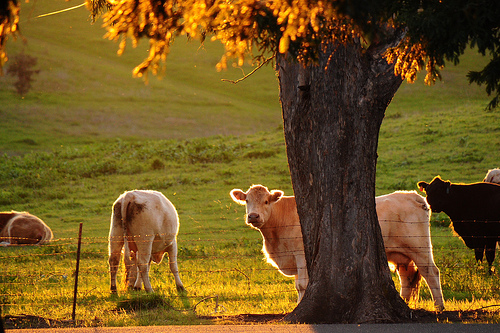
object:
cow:
[417, 174, 500, 276]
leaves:
[83, 0, 500, 114]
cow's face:
[229, 183, 284, 227]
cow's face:
[416, 174, 452, 213]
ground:
[0, 49, 485, 191]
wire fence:
[0, 219, 499, 313]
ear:
[271, 190, 285, 203]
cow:
[0, 210, 53, 246]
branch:
[221, 55, 276, 85]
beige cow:
[228, 183, 445, 313]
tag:
[420, 186, 424, 192]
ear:
[417, 181, 429, 188]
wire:
[0, 219, 500, 311]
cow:
[106, 188, 188, 293]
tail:
[121, 192, 133, 282]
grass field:
[0, 3, 498, 333]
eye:
[265, 201, 268, 205]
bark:
[279, 60, 411, 324]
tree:
[80, 0, 499, 324]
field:
[18, 97, 178, 186]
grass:
[0, 1, 497, 328]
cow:
[482, 168, 500, 182]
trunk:
[274, 47, 413, 325]